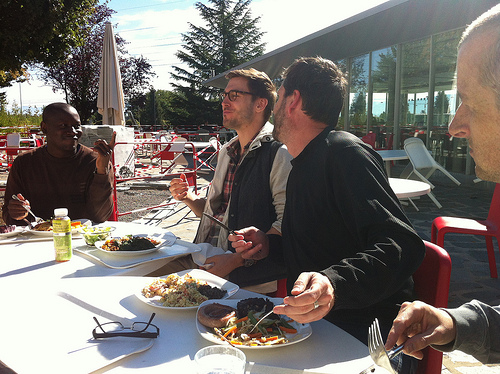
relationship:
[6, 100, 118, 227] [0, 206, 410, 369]
man sitting around table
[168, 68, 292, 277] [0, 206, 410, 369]
man sitting around table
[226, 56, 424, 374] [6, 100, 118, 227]
man sitting around man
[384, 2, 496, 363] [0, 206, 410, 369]
man sitting around table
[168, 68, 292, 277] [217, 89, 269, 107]
man wearing eyeglasses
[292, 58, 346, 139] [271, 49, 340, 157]
hair on head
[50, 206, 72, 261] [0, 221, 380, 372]
beverage bottle on table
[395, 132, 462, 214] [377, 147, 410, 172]
chair leaning on table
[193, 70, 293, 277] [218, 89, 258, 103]
man wearing eyeglasses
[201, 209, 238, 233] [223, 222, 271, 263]
knife in right hand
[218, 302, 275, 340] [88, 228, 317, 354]
food on plates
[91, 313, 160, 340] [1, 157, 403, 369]
eyeglasses are on table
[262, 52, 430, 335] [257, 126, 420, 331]
man wearing a shirt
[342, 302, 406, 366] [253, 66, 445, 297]
fork in man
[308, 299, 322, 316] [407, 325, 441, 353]
ring around finger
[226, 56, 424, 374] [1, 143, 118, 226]
man on brown shirt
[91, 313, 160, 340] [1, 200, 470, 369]
eyeglasses on table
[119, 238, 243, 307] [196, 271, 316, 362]
plate full food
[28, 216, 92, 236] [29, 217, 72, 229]
white plate full food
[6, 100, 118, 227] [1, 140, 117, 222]
man in brown shirt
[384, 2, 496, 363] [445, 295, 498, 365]
man in shirt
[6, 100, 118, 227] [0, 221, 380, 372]
man at table